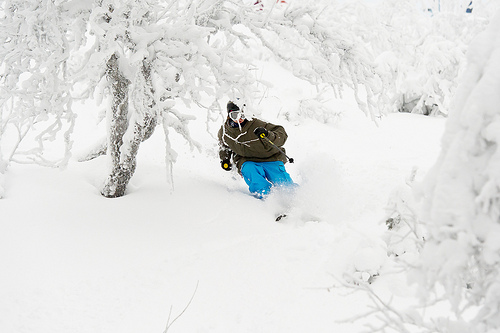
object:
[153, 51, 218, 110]
branches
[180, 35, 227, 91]
snow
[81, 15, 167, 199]
tree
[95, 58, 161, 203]
trunk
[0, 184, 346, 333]
snow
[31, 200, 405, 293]
ground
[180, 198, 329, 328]
slope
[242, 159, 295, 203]
pants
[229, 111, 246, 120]
goggles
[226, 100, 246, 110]
hat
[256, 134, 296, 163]
pole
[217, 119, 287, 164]
coat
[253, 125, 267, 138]
gloves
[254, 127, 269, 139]
hands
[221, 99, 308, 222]
man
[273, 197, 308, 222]
skis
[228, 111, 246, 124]
mask